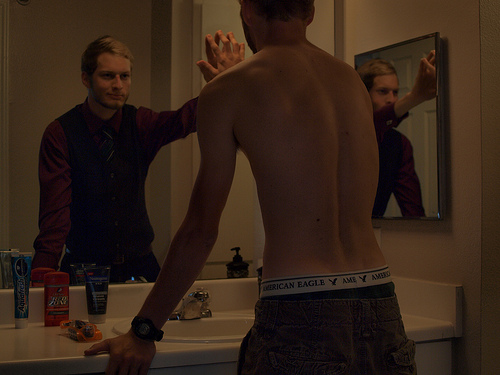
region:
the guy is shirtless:
[271, 85, 326, 157]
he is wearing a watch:
[127, 308, 165, 347]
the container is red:
[41, 270, 72, 312]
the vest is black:
[77, 163, 99, 197]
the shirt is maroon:
[47, 178, 63, 212]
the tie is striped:
[98, 126, 113, 157]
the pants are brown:
[296, 326, 335, 336]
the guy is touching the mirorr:
[198, 23, 248, 71]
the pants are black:
[143, 261, 160, 274]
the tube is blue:
[5, 245, 35, 305]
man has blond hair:
[75, 37, 159, 81]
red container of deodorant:
[41, 273, 71, 328]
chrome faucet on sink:
[167, 285, 219, 332]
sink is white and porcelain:
[165, 277, 290, 365]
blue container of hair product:
[67, 257, 112, 325]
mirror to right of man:
[367, 54, 431, 244]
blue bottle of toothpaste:
[5, 250, 36, 347]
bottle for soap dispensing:
[212, 218, 246, 279]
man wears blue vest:
[35, 98, 146, 258]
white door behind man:
[172, 30, 213, 261]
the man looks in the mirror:
[74, 0, 414, 370]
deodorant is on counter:
[41, 272, 71, 324]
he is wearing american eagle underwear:
[263, 268, 389, 291]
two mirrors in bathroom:
[0, 3, 445, 284]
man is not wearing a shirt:
[85, 0, 399, 368]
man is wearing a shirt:
[28, 74, 211, 276]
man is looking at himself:
[86, 47, 126, 103]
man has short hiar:
[81, 45, 133, 82]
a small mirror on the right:
[364, 37, 449, 233]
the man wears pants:
[237, 283, 414, 370]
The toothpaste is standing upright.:
[1, 228, 47, 365]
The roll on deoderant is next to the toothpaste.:
[6, 244, 83, 338]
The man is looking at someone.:
[0, 0, 430, 371]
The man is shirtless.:
[75, 0, 425, 370]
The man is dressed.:
[20, 25, 240, 290]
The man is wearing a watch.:
[75, 0, 420, 370]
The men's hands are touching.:
[25, 0, 420, 374]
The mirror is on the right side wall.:
[336, 4, 496, 371]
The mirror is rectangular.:
[343, 22, 468, 235]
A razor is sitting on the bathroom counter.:
[1, 255, 258, 373]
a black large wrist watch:
[124, 313, 166, 343]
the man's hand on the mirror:
[191, 23, 250, 90]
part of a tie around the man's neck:
[92, 118, 122, 170]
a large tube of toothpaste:
[7, 244, 38, 334]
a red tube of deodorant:
[38, 262, 72, 337]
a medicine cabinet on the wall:
[336, 19, 459, 239]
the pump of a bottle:
[223, 242, 245, 262]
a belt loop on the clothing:
[351, 298, 378, 341]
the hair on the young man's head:
[76, 29, 140, 74]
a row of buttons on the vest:
[106, 165, 126, 252]